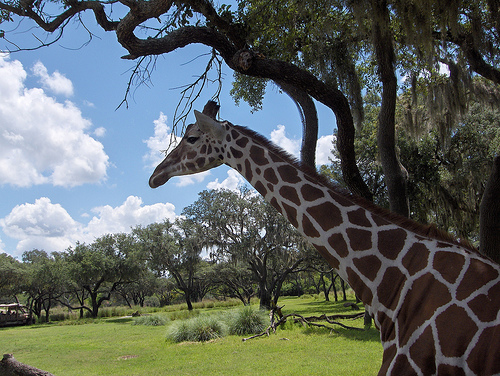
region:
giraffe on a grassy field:
[130, 93, 497, 372]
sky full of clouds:
[7, 73, 120, 202]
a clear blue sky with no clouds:
[109, 94, 151, 136]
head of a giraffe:
[142, 98, 235, 203]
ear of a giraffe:
[182, 92, 225, 124]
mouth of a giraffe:
[141, 124, 188, 190]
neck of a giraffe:
[255, 148, 411, 308]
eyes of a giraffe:
[185, 131, 199, 143]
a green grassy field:
[70, 344, 208, 368]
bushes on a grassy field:
[149, 295, 281, 355]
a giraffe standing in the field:
[150, 108, 499, 373]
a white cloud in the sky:
[8, 71, 110, 186]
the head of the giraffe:
[148, 104, 228, 191]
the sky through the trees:
[347, 48, 447, 113]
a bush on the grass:
[150, 308, 287, 336]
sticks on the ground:
[264, 298, 353, 335]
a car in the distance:
[5, 304, 40, 321]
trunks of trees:
[232, 30, 441, 213]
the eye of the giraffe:
[186, 136, 205, 140]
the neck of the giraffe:
[229, 131, 401, 318]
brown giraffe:
[158, 116, 473, 356]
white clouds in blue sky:
[15, 59, 67, 130]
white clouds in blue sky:
[25, 89, 89, 130]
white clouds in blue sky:
[71, 69, 138, 106]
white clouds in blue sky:
[162, 45, 197, 87]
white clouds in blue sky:
[44, 73, 88, 105]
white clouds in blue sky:
[42, 138, 114, 183]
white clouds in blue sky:
[42, 62, 130, 123]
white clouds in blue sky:
[5, 133, 47, 201]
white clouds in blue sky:
[7, 93, 109, 175]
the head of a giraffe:
[93, 52, 330, 251]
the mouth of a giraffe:
[134, 160, 174, 194]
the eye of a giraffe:
[176, 131, 208, 156]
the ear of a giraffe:
[177, 110, 227, 157]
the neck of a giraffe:
[207, 105, 432, 295]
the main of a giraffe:
[225, 85, 420, 205]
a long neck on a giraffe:
[203, 105, 418, 267]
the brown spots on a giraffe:
[168, 139, 397, 302]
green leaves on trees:
[126, 211, 301, 300]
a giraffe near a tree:
[171, 122, 422, 362]